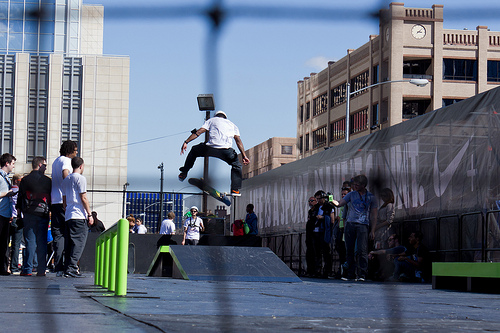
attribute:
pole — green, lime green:
[88, 214, 139, 305]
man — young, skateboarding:
[173, 110, 253, 198]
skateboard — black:
[186, 175, 234, 207]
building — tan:
[2, 2, 137, 210]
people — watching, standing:
[2, 133, 95, 280]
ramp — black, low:
[144, 243, 307, 286]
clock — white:
[407, 22, 429, 46]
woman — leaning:
[366, 185, 400, 286]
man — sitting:
[389, 224, 433, 285]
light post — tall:
[153, 158, 167, 240]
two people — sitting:
[382, 224, 431, 281]